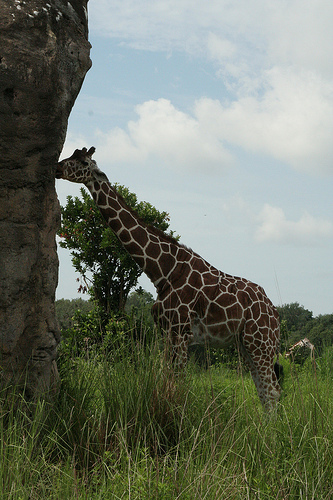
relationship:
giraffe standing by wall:
[55, 146, 284, 417] [1, 2, 94, 414]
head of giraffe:
[53, 145, 102, 185] [55, 146, 284, 417]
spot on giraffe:
[156, 252, 177, 279] [55, 146, 284, 417]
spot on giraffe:
[116, 209, 139, 230] [55, 146, 284, 417]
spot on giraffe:
[188, 256, 210, 273] [55, 146, 284, 417]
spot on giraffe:
[213, 292, 240, 308] [55, 146, 284, 417]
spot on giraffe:
[174, 284, 200, 306] [55, 146, 284, 417]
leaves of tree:
[56, 184, 182, 275] [59, 182, 181, 352]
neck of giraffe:
[80, 177, 185, 293] [55, 146, 284, 417]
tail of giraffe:
[271, 337, 286, 384] [55, 146, 284, 417]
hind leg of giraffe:
[238, 306, 283, 416] [55, 146, 284, 417]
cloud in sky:
[248, 200, 332, 248] [57, 1, 332, 308]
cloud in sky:
[60, 97, 244, 179] [57, 1, 332, 308]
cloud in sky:
[195, 63, 332, 169] [57, 1, 332, 308]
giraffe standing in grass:
[55, 146, 284, 417] [1, 326, 332, 499]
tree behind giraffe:
[59, 182, 181, 352] [55, 146, 284, 417]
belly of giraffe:
[186, 298, 244, 354] [55, 146, 284, 417]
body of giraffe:
[154, 244, 280, 350] [55, 146, 284, 417]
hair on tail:
[271, 362, 283, 383] [271, 337, 286, 384]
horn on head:
[87, 146, 96, 156] [53, 145, 102, 185]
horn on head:
[80, 144, 88, 153] [53, 145, 102, 185]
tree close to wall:
[59, 182, 181, 352] [1, 2, 94, 414]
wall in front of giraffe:
[1, 2, 94, 414] [55, 146, 284, 417]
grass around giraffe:
[1, 326, 332, 499] [55, 146, 284, 417]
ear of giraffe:
[88, 168, 115, 184] [55, 146, 284, 417]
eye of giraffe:
[80, 159, 89, 169] [55, 146, 284, 417]